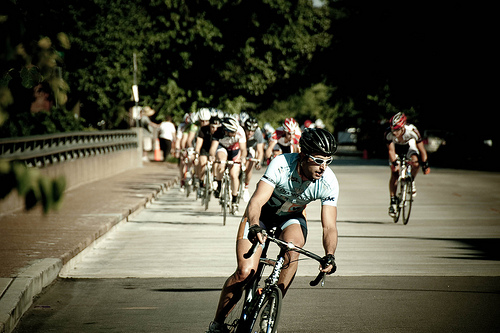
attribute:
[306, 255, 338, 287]
gloves — black 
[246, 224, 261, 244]
gloves — black 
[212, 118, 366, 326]
man — leaning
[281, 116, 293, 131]
helmet — white , red 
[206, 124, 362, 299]
man — pictured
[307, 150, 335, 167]
sunglasses — white 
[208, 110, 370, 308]
man — leading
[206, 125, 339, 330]
racer — lead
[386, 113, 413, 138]
helmet — red , silver 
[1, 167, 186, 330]
sidewalk — brown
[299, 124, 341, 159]
helmet — black